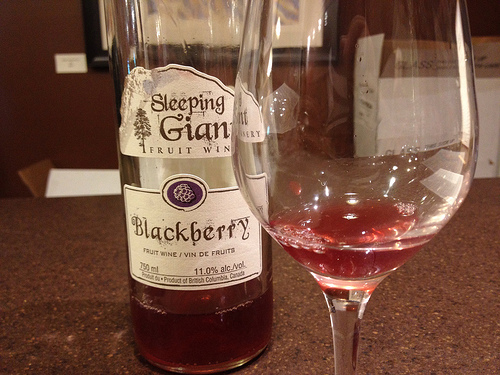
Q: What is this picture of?
A: A beverage.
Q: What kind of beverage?
A: Wine.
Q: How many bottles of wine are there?
A: One.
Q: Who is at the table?
A: Noone.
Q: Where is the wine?
A: On the table.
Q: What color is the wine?
A: Red.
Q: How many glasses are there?
A: One.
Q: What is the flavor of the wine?
A: Blackberry.